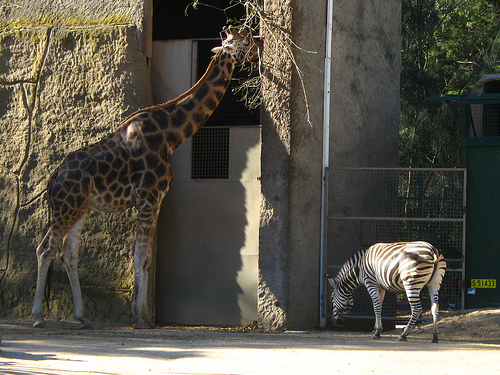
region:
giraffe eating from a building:
[29, 18, 261, 338]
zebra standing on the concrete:
[312, 227, 449, 349]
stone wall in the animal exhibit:
[0, 1, 147, 331]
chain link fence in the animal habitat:
[323, 150, 467, 328]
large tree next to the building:
[407, 2, 499, 241]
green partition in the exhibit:
[436, 88, 499, 310]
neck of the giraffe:
[152, 45, 241, 142]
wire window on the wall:
[187, 125, 237, 186]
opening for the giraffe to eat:
[144, 10, 260, 128]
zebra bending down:
[322, 225, 449, 345]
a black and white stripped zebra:
[325, 238, 445, 340]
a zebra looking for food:
[323, 240, 448, 345]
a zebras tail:
[403, 246, 438, 265]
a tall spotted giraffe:
[32, 24, 264, 333]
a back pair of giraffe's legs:
[33, 155, 88, 330]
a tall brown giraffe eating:
[28, 24, 264, 327]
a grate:
[189, 127, 231, 180]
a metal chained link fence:
[319, 163, 469, 323]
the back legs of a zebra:
[398, 251, 443, 341]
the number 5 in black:
[475, 277, 482, 288]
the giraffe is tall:
[31, 33, 253, 325]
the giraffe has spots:
[32, 31, 259, 329]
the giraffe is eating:
[26, 26, 266, 331]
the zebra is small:
[325, 240, 443, 335]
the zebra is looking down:
[325, 245, 445, 342]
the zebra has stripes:
[330, 241, 445, 342]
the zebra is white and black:
[324, 240, 445, 340]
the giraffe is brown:
[31, 33, 258, 326]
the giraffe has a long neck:
[153, 33, 248, 135]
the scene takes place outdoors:
[1, 0, 496, 347]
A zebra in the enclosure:
[329, 239, 444, 341]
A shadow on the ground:
[8, 323, 448, 362]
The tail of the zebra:
[407, 247, 438, 264]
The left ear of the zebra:
[327, 276, 336, 286]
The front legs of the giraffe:
[121, 203, 164, 327]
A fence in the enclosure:
[325, 168, 499, 317]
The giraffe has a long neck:
[141, 49, 238, 148]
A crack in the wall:
[6, 25, 132, 206]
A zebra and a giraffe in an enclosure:
[33, 25, 446, 339]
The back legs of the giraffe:
[32, 213, 89, 330]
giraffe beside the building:
[9, 22, 262, 327]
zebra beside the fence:
[327, 240, 468, 335]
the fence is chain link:
[315, 164, 463, 311]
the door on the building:
[169, 122, 261, 326]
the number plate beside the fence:
[465, 274, 493, 292]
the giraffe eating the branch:
[34, 19, 271, 331]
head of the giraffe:
[215, 25, 271, 65]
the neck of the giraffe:
[165, 55, 233, 144]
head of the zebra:
[320, 273, 355, 330]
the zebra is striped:
[320, 240, 459, 345]